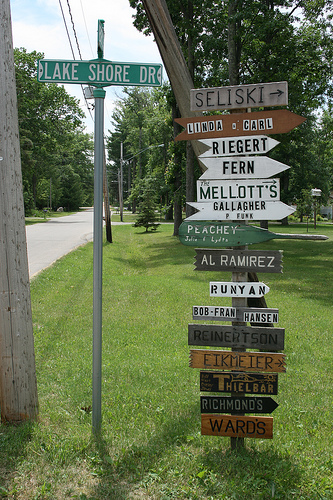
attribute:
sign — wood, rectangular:
[185, 77, 293, 116]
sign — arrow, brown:
[171, 108, 308, 144]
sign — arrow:
[196, 133, 286, 159]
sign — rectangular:
[195, 176, 284, 204]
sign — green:
[33, 56, 165, 92]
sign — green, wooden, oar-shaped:
[173, 219, 280, 249]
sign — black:
[197, 393, 281, 416]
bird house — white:
[310, 186, 324, 199]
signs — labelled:
[173, 80, 309, 441]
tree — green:
[13, 47, 77, 218]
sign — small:
[208, 277, 272, 301]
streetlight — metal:
[116, 138, 167, 226]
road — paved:
[21, 199, 114, 294]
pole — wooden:
[2, 0, 42, 429]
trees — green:
[106, 1, 331, 235]